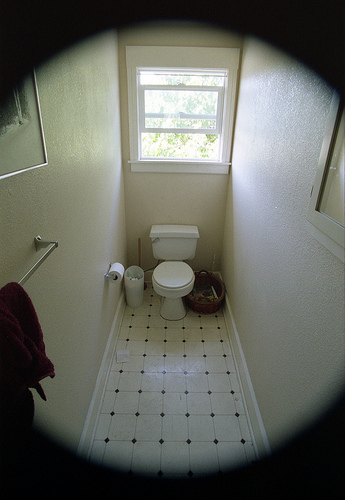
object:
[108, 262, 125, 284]
toilet paper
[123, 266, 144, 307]
garbage can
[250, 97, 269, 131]
ground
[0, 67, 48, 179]
picture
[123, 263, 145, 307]
trash can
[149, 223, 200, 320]
toilet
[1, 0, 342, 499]
bathroom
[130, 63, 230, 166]
frame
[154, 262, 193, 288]
lid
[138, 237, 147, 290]
plunger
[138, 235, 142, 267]
handle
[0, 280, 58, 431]
towel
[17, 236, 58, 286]
rack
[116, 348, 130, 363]
tissue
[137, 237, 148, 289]
toilet plunger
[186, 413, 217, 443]
tile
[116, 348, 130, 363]
toilet paper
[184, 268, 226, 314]
basket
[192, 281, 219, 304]
magazines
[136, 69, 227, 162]
window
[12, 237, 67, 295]
towel rack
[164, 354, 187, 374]
diamonds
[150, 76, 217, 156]
vegetation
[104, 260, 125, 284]
holder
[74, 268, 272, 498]
base board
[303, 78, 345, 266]
cabinet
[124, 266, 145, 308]
can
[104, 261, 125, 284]
tissue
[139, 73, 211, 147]
outside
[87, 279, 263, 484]
floor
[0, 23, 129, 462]
wall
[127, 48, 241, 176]
trimming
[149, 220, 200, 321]
stool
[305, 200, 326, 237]
corner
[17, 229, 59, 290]
bar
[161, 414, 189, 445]
design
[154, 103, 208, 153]
sun